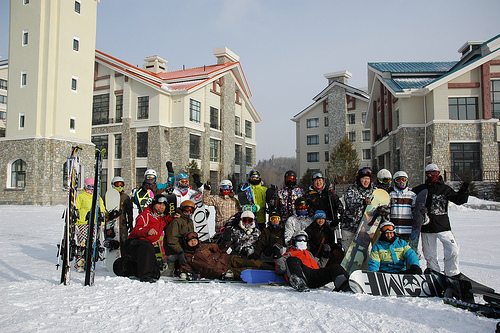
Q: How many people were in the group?
A: 21.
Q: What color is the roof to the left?
A: Pink.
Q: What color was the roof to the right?
A: Blue.